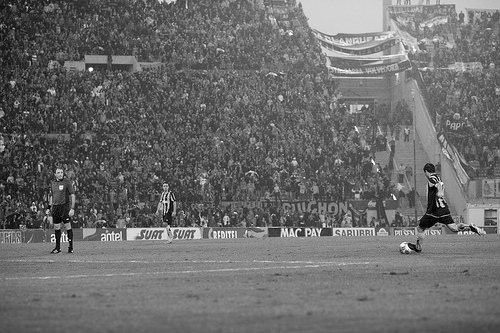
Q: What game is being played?
A: Soccer.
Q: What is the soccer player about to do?
A: Kick the ball.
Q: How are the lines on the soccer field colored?
A: White.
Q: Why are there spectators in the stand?
A: To watch the soccer.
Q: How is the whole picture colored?
A: Black and white.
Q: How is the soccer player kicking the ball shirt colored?
A: Black.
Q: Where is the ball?
A: On the field.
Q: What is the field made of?
A: Grass.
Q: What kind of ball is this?
A: Soccer ball.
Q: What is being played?
A: Soccer.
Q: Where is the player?
A: Behind the ball.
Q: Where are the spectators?
A: In the stands.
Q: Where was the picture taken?
A: In a stadium.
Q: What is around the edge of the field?
A: Advertisements.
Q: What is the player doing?
A: Kicking the ball.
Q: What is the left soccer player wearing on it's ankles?
A: It's socks.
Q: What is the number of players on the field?
A: It's two.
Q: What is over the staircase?
A: It's banners.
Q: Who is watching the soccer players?
A: It's fans.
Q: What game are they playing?
A: Soccer.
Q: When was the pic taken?
A: During the day.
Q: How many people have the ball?
A: 1.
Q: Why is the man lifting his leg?
A: He is about to kick the ball.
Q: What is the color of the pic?
A: Black and white.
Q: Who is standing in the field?
A: Referee.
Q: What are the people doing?
A: Cheering.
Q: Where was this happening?
A: Field.